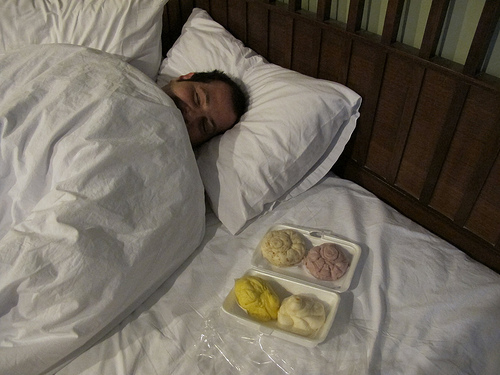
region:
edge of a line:
[267, 312, 288, 351]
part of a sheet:
[360, 273, 382, 350]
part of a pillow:
[58, 217, 100, 267]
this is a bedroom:
[20, 5, 429, 346]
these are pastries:
[264, 215, 341, 344]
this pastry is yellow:
[238, 283, 275, 321]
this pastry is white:
[284, 298, 330, 370]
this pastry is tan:
[265, 223, 307, 282]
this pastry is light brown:
[309, 230, 335, 287]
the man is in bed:
[86, 40, 275, 197]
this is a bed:
[46, 2, 446, 288]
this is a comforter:
[38, 48, 168, 240]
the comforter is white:
[14, 93, 161, 228]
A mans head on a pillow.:
[157, 70, 250, 157]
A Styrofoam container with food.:
[218, 223, 362, 351]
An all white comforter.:
[0, 44, 207, 374]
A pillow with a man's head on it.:
[157, 8, 362, 236]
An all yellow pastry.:
[230, 273, 279, 320]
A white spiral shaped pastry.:
[278, 294, 325, 336]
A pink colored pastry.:
[304, 242, 352, 282]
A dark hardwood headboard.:
[161, 0, 498, 277]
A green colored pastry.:
[260, 227, 305, 265]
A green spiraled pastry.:
[261, 228, 306, 265]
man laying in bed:
[28, 14, 449, 349]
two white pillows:
[11, 5, 380, 283]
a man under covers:
[73, 25, 400, 277]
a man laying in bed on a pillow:
[18, 12, 445, 337]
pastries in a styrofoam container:
[195, 175, 418, 351]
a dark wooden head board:
[276, 8, 499, 298]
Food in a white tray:
[228, 205, 330, 345]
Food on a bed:
[231, 210, 347, 361]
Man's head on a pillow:
[145, 61, 257, 145]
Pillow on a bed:
[146, 14, 363, 224]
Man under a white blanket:
[13, 20, 276, 329]